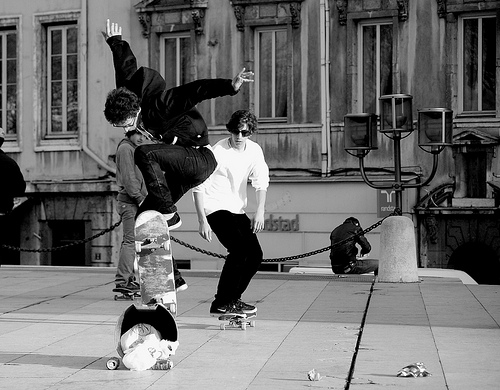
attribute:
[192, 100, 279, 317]
man — young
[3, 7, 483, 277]
building — nearby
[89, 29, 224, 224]
man — young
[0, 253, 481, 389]
sidewalk — grey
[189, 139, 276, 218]
shirt — long sleeve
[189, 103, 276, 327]
man whole — young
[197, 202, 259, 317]
pants — black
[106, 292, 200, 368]
garbage — turned over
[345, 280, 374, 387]
crack — large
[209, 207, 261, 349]
pants — long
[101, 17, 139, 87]
arm — out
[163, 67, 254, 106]
arm — out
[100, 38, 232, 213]
hoodie — black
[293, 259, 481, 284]
wall — concrete